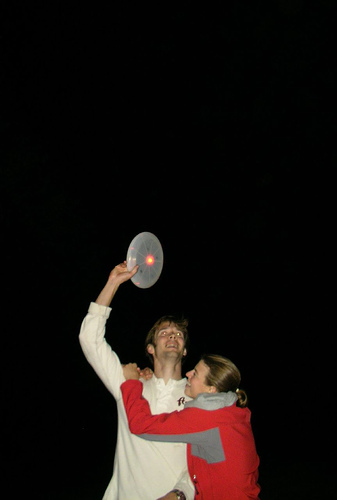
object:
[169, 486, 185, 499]
watch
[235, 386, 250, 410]
ponytail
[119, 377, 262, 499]
clothing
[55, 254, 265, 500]
couple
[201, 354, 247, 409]
hair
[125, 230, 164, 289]
disc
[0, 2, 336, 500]
photo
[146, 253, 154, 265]
light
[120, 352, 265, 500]
woman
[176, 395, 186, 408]
logo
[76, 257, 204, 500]
man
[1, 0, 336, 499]
sky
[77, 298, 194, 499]
shirt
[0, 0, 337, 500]
night